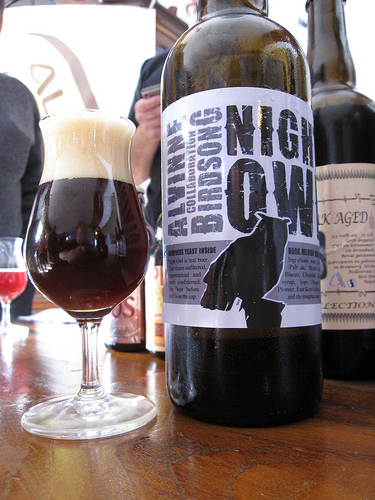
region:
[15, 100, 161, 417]
beer in glass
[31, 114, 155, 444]
brown beer in glass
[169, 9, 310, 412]
glass brown beer bottle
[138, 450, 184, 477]
tan and brown wooden table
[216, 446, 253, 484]
tan and brown wooden table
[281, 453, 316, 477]
tan and brown wooden table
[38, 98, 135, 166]
top of the drink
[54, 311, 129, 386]
handle of the drink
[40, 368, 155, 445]
bottom of the drink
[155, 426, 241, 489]
brown table under the drink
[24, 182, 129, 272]
reflection in the cup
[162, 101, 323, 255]
word on the glass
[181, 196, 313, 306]
owl design on the bottle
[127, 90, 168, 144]
hand of a person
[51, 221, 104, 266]
reflection of a man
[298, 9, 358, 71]
top of the bottle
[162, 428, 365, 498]
the table is brown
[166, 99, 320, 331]
the label is white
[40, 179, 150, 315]
the drink is brown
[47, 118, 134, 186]
foam on top of drink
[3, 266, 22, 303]
the liquid is red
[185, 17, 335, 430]
bottle on the table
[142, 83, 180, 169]
cellphone in the hand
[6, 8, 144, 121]
the banner is white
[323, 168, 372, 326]
the label is tan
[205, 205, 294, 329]
graphic on the label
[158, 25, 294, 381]
grey and white label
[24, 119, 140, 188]
white head on beer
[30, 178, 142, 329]
brown beer in glass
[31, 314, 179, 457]
glass has round base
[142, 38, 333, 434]
tall and brown bottle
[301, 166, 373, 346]
black and tan label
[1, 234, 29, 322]
glass of red wine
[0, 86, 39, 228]
person has grey shirt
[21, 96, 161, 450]
glass is full of a dark beer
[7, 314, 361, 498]
Goblet is on a wooden counter top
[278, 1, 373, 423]
Bottle sits behind the bottle of dark beer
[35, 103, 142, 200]
Beer glass has a large head on it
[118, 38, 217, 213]
A man is holding his phone behind the counter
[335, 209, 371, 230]
The word "aged" is seen on the bottle of beer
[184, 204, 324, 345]
outline of an owl is on the bottle label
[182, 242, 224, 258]
Yeast inside appears on the side of the bottle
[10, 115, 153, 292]
glass on the table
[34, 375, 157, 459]
bottom of the glass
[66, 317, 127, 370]
handle of the glass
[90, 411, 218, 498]
lines on the table